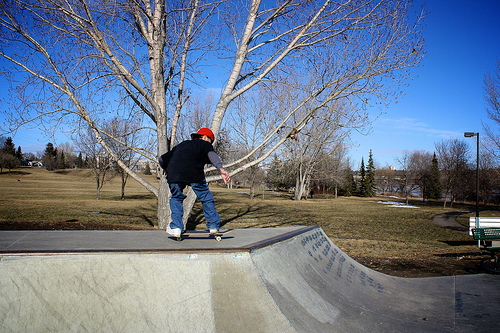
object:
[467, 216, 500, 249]
bench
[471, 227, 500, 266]
bench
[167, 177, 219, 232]
jeans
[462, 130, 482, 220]
streetlamp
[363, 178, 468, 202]
river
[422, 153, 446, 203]
trees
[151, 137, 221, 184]
sweater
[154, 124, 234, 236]
boy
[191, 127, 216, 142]
cap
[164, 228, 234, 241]
skateboard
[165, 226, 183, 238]
tennis shoes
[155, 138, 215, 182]
shirt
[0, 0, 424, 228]
tree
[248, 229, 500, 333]
skateboard ramp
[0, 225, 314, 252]
skateboard park